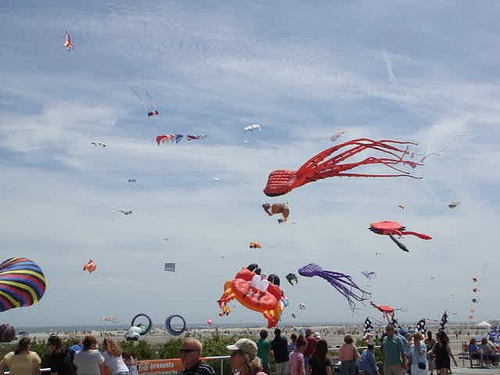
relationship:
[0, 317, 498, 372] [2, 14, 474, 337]
people flying kites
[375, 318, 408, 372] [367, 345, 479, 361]
man walking on road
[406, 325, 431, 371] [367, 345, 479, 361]
wife walking on road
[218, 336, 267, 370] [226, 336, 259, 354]
woman in baseball cap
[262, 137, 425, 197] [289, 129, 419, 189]
red kite with tails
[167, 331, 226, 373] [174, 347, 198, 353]
man wearing sunglasses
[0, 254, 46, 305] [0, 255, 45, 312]
kite with multicolored stripes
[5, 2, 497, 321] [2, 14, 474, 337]
sky full of kites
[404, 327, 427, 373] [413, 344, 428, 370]
woman carrying black purse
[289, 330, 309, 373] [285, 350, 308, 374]
woman in pink shirt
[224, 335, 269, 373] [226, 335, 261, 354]
lady wearing hat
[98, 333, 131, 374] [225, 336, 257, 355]
woman with lid